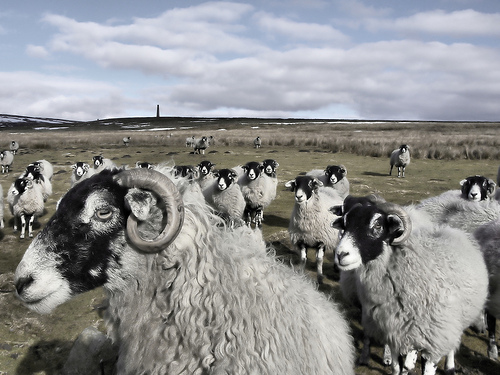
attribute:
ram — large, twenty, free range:
[12, 160, 491, 375]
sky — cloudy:
[0, 0, 500, 124]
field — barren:
[6, 147, 496, 371]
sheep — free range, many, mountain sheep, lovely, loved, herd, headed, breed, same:
[0, 126, 498, 374]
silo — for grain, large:
[156, 102, 163, 116]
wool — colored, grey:
[169, 260, 304, 357]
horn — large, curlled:
[113, 162, 185, 252]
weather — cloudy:
[5, 7, 494, 372]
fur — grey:
[411, 251, 468, 304]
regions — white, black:
[15, 176, 388, 315]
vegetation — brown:
[5, 132, 500, 165]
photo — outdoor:
[0, 1, 496, 375]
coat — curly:
[386, 142, 415, 182]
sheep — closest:
[13, 165, 356, 374]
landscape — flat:
[9, 129, 500, 374]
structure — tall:
[148, 98, 169, 118]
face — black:
[10, 175, 27, 199]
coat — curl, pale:
[4, 173, 60, 245]